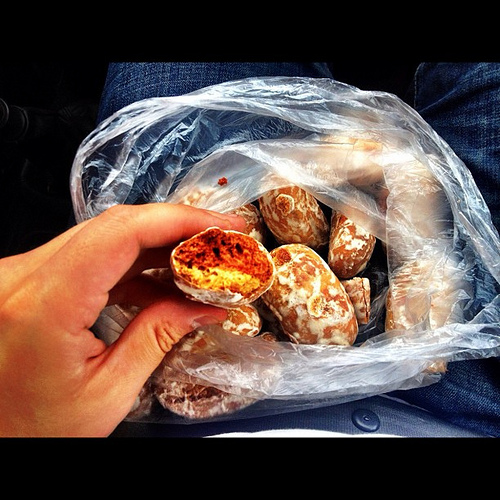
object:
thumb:
[141, 296, 224, 351]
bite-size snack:
[168, 225, 278, 305]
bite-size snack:
[264, 242, 359, 349]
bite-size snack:
[330, 206, 376, 273]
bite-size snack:
[260, 180, 329, 240]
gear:
[7, 79, 67, 165]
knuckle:
[155, 324, 181, 354]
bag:
[69, 74, 500, 426]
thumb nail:
[191, 312, 221, 327]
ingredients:
[179, 264, 252, 295]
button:
[353, 408, 383, 430]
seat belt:
[192, 396, 496, 438]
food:
[177, 301, 261, 354]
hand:
[0, 200, 245, 438]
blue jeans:
[46, 56, 498, 408]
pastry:
[343, 278, 370, 326]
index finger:
[33, 203, 253, 334]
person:
[6, 55, 496, 437]